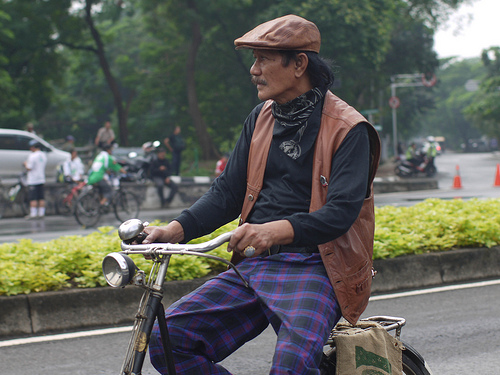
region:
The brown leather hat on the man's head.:
[232, 15, 326, 57]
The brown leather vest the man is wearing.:
[243, 100, 382, 312]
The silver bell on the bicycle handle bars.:
[113, 209, 150, 244]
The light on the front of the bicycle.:
[94, 241, 138, 291]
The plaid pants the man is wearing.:
[168, 226, 333, 374]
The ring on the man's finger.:
[243, 241, 257, 261]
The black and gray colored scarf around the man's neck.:
[258, 92, 323, 124]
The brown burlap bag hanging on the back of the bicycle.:
[336, 320, 407, 374]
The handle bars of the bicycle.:
[118, 228, 250, 255]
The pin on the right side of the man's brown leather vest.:
[316, 173, 333, 188]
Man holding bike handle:
[229, 206, 298, 262]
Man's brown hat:
[231, 12, 326, 56]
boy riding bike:
[90, 143, 155, 227]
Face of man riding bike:
[222, 15, 347, 114]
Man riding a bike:
[177, 15, 386, 367]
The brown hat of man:
[214, 12, 343, 52]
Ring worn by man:
[242, 240, 259, 262]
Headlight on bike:
[91, 242, 144, 297]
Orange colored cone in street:
[447, 161, 464, 189]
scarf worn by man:
[262, 91, 334, 179]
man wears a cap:
[211, 9, 378, 166]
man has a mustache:
[232, 51, 297, 111]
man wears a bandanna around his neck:
[228, 41, 326, 160]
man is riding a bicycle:
[93, 201, 388, 371]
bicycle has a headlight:
[79, 249, 162, 304]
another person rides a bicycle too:
[18, 129, 135, 227]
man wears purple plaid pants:
[126, 259, 332, 362]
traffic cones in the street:
[431, 152, 497, 201]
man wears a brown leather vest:
[224, 99, 409, 322]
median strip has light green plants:
[390, 194, 492, 296]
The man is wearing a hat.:
[227, 16, 320, 51]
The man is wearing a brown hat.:
[220, 12, 325, 53]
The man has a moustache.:
[247, 75, 272, 86]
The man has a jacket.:
[235, 96, 385, 331]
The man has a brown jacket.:
[227, 102, 387, 322]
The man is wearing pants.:
[112, 245, 344, 370]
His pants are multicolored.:
[170, 220, 350, 370]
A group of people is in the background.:
[3, 20, 183, 217]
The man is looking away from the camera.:
[236, 20, 326, 110]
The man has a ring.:
[244, 235, 258, 264]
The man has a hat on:
[220, 14, 337, 81]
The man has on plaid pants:
[141, 220, 316, 374]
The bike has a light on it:
[86, 246, 159, 303]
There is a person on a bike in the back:
[14, 107, 308, 235]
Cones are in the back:
[441, 153, 498, 196]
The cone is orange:
[445, 157, 475, 203]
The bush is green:
[401, 203, 498, 240]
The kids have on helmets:
[22, 128, 180, 167]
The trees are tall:
[76, 21, 245, 177]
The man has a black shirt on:
[270, 158, 397, 284]